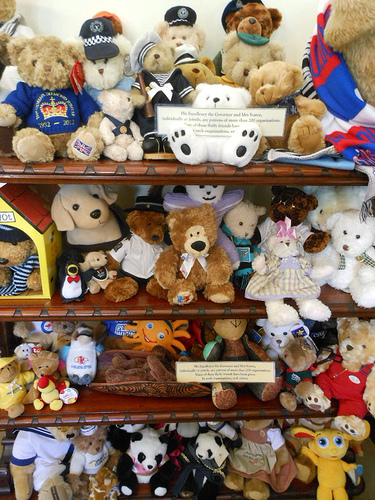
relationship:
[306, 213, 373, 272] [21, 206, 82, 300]
bear in box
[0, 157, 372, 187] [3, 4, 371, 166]
shelf with stuffed animals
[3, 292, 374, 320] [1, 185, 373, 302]
shelf with stuffed animals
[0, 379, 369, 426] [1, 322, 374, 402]
shelf with stuffed animals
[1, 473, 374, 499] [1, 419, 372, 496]
shelf with stuffed animals